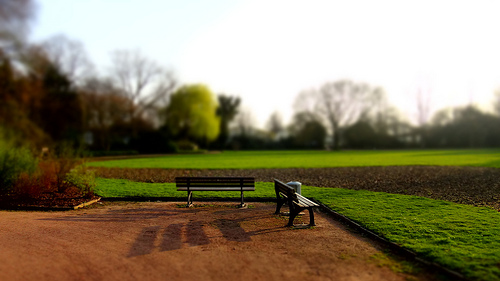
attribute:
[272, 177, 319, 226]
bench — brown, wooden, made out of wood, park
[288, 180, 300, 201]
trash can — silver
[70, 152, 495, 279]
grass — green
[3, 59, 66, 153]
tree — colorful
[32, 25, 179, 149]
tree — large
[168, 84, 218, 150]
tree — green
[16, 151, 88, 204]
bushes — red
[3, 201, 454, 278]
field — brown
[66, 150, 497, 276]
field — green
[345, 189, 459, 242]
grass — green